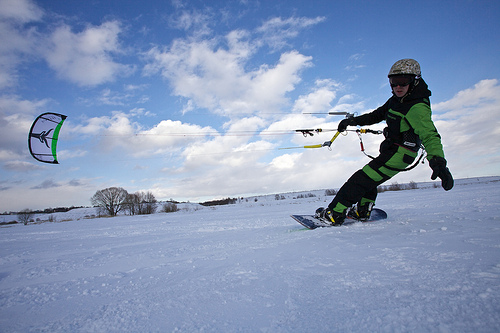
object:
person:
[317, 56, 454, 225]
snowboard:
[290, 207, 390, 229]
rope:
[355, 134, 427, 173]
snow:
[0, 178, 500, 333]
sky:
[0, 0, 497, 212]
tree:
[92, 186, 129, 215]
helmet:
[387, 58, 422, 77]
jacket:
[349, 95, 446, 160]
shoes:
[315, 207, 372, 226]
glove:
[429, 159, 455, 192]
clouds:
[151, 20, 335, 113]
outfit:
[330, 93, 444, 215]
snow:
[303, 215, 328, 226]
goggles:
[389, 76, 413, 86]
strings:
[59, 128, 338, 140]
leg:
[323, 145, 421, 216]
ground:
[0, 179, 497, 333]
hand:
[337, 119, 350, 132]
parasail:
[26, 111, 65, 164]